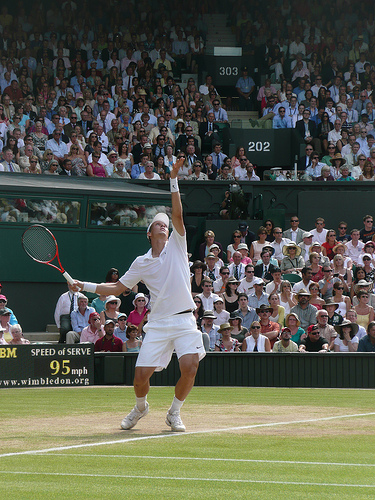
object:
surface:
[3, 388, 366, 499]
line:
[1, 410, 373, 460]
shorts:
[136, 311, 204, 374]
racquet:
[18, 220, 81, 292]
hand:
[66, 276, 84, 295]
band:
[169, 176, 180, 194]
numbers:
[247, 140, 256, 153]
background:
[2, 7, 375, 214]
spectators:
[109, 160, 131, 179]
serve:
[30, 153, 201, 344]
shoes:
[119, 400, 149, 434]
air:
[20, 8, 375, 496]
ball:
[141, 322, 149, 333]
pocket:
[141, 321, 151, 338]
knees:
[132, 373, 149, 388]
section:
[254, 11, 373, 175]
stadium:
[6, 8, 375, 487]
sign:
[4, 343, 92, 389]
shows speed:
[48, 358, 87, 379]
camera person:
[220, 183, 248, 219]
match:
[12, 66, 349, 478]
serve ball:
[120, 119, 202, 275]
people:
[284, 214, 307, 240]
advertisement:
[3, 376, 92, 388]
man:
[93, 163, 201, 429]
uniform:
[117, 229, 205, 364]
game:
[0, 160, 351, 497]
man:
[241, 263, 265, 291]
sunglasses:
[246, 270, 255, 273]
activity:
[7, 10, 372, 492]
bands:
[83, 282, 98, 294]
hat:
[146, 212, 170, 236]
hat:
[335, 317, 360, 334]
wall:
[0, 345, 359, 387]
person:
[216, 164, 235, 181]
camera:
[229, 182, 240, 196]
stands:
[2, 5, 368, 385]